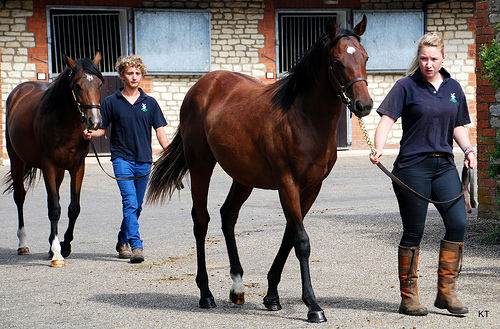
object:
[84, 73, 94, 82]
spot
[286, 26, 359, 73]
mane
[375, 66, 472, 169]
shirt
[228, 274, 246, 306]
white foot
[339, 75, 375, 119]
horse break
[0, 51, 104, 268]
horse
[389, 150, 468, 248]
pants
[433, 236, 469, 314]
boots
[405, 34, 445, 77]
head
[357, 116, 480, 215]
lead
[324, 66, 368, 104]
bridle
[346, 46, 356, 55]
spot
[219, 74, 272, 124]
back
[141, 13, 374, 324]
horse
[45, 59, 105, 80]
mane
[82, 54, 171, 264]
boy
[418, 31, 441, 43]
hair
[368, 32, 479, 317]
girl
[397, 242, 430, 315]
boots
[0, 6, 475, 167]
building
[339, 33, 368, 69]
forehead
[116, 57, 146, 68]
hair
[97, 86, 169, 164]
shirt